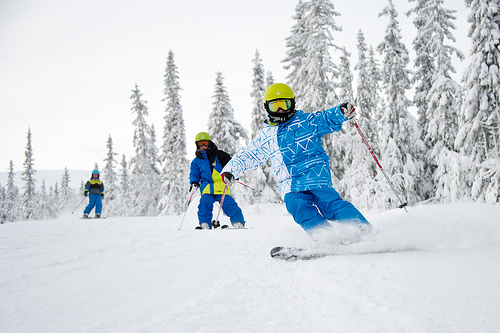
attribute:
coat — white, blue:
[221, 101, 350, 203]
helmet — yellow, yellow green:
[263, 83, 296, 126]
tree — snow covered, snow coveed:
[122, 83, 160, 218]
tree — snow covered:
[154, 50, 194, 216]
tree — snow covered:
[282, 1, 349, 198]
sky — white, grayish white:
[1, 1, 477, 171]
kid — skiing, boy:
[221, 83, 392, 248]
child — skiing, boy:
[190, 133, 247, 231]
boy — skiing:
[80, 167, 106, 219]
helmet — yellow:
[194, 132, 210, 143]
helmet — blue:
[92, 167, 101, 175]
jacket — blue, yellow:
[189, 144, 238, 198]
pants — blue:
[283, 189, 376, 238]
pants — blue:
[197, 193, 246, 227]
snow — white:
[1, 200, 498, 326]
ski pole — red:
[352, 116, 408, 214]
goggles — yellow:
[264, 99, 297, 116]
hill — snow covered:
[2, 169, 131, 196]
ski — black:
[268, 244, 426, 259]